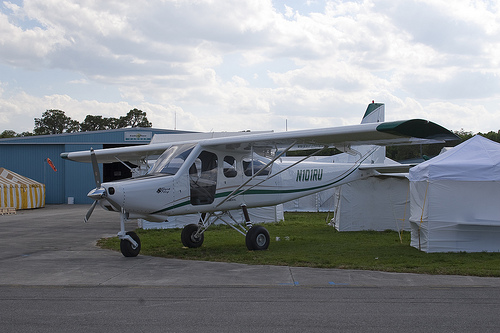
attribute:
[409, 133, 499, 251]
tent — white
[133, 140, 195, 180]
window — large, glass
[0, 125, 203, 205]
garage — large, wide, metal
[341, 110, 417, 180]
tail — large, tall, white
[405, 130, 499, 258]
tent — short, white, plastic